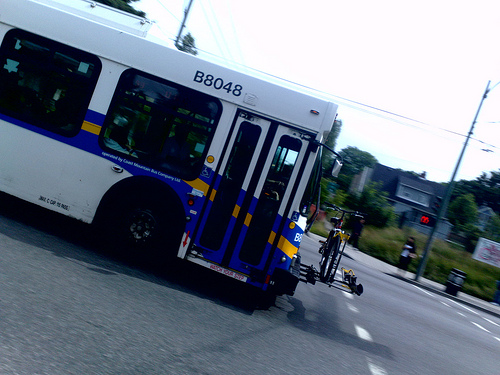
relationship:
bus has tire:
[4, 2, 366, 316] [103, 186, 186, 265]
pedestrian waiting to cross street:
[396, 234, 418, 277] [330, 257, 499, 374]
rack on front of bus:
[308, 225, 366, 310] [4, 2, 366, 316]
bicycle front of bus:
[316, 202, 366, 284] [5, 3, 367, 349]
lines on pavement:
[337, 292, 393, 373] [275, 205, 483, 360]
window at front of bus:
[120, 75, 219, 175] [47, 5, 359, 308]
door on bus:
[187, 107, 318, 286] [27, 22, 347, 306]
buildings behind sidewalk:
[329, 143, 457, 233] [304, 231, 496, 310]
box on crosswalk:
[444, 255, 469, 300] [371, 242, 499, 373]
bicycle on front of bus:
[316, 197, 361, 293] [5, 3, 367, 349]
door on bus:
[189, 99, 322, 293] [5, 3, 367, 349]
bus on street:
[4, 0, 339, 298] [1, 218, 499, 372]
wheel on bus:
[102, 183, 178, 265] [5, 3, 367, 349]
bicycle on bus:
[316, 202, 366, 284] [2, 23, 356, 274]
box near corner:
[444, 267, 469, 297] [347, 170, 429, 278]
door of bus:
[189, 99, 322, 293] [5, 3, 367, 349]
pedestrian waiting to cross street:
[399, 237, 417, 271] [371, 288, 448, 360]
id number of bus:
[192, 69, 242, 96] [5, 3, 367, 349]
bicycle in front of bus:
[316, 202, 366, 284] [4, 2, 366, 316]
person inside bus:
[160, 127, 197, 182] [4, 2, 366, 316]